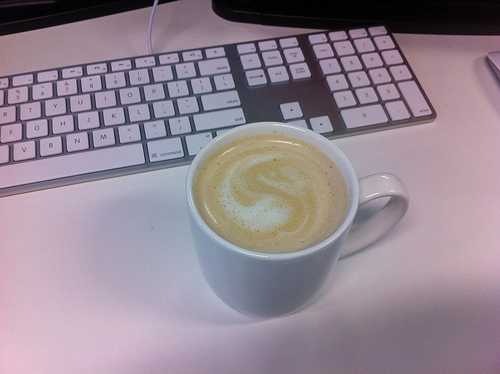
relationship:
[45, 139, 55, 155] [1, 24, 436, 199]
letter on keyboard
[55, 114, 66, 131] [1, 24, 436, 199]
letter on keyboard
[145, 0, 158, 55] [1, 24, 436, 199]
cord attached to keyboard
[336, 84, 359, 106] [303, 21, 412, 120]
key on a keyboard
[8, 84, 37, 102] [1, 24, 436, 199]
key on keyboard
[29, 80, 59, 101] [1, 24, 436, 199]
key on keyboard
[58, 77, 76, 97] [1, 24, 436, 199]
key on keyboard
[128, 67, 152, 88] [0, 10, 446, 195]
key on keyboard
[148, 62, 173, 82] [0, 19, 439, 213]
key on keyboard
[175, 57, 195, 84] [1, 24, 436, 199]
key on keyboard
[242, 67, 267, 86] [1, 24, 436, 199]
key on a keyboard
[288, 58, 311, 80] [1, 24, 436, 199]
key on a keyboard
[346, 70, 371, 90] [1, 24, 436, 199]
key on  a keyboard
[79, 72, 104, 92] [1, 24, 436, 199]
key on a keyboard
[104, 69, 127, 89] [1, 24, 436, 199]
key on a keyboard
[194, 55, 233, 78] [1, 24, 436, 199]
key on a keyboard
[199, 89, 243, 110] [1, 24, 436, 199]
key on a keyboard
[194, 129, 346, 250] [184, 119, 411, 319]
liquid in the cup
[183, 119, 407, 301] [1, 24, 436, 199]
cup near the keyboard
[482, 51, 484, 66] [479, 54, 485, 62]
corner of the mouse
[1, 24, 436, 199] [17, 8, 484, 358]
keyboard on the desk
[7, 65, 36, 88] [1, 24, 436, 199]
key on keyboard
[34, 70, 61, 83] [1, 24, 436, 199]
key on keyboard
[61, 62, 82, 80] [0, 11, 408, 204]
key on keyboard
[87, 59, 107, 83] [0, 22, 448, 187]
key on keyboard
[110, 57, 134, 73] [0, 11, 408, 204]
key on keyboard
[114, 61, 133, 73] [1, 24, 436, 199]
key on keyboard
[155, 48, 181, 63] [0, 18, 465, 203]
key on keyboard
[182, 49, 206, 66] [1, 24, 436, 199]
key on keyboard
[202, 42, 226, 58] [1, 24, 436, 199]
key on keyboard